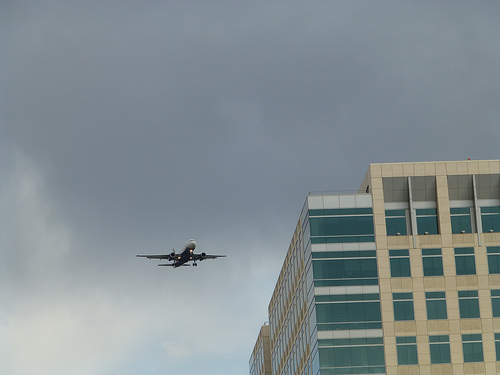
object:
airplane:
[135, 238, 227, 269]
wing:
[188, 254, 226, 262]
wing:
[136, 253, 181, 262]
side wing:
[157, 263, 173, 266]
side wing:
[181, 264, 192, 267]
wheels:
[195, 263, 198, 267]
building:
[247, 158, 500, 374]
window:
[327, 259, 346, 279]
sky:
[1, 1, 499, 373]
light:
[177, 256, 181, 260]